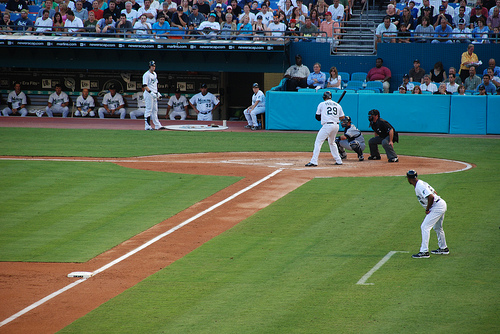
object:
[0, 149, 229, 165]
line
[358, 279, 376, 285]
line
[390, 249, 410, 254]
line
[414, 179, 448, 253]
uniform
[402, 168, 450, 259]
baseball player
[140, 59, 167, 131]
baseball player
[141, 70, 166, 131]
uniform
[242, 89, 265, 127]
uniform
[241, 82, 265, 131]
baseball player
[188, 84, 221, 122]
baseball player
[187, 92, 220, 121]
uniform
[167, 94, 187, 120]
uniform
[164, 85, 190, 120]
baseball player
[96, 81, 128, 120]
baseball player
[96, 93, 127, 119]
uniform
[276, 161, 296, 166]
plate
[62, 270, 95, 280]
third base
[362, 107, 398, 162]
umpire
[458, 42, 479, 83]
man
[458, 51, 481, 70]
shirt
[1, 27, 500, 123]
bull pen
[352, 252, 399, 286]
lines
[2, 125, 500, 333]
grass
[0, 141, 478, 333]
dirt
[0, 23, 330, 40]
rails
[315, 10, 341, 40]
crowd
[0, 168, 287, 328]
line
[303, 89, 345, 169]
baseball player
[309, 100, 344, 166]
uniform